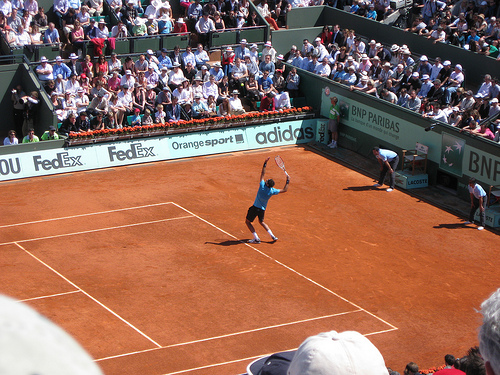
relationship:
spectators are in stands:
[34, 54, 54, 81] [24, 49, 310, 129]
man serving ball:
[243, 157, 291, 243] [266, 155, 275, 160]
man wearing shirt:
[243, 155, 291, 243] [251, 175, 280, 211]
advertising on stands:
[1, 118, 330, 180] [1, 0, 298, 145]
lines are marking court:
[0, 202, 399, 358] [1, 139, 498, 357]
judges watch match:
[372, 142, 489, 231] [77, 146, 373, 312]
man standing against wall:
[326, 94, 340, 152] [276, 59, 498, 212]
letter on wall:
[465, 147, 482, 178] [291, 66, 498, 220]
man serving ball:
[243, 155, 291, 243] [212, 95, 303, 168]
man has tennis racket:
[243, 157, 291, 243] [273, 152, 289, 177]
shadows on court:
[346, 180, 391, 197] [1, 139, 498, 357]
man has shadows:
[371, 144, 401, 192] [346, 180, 391, 197]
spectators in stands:
[0, 5, 497, 135] [3, 2, 497, 191]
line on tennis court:
[12, 192, 213, 252] [9, 146, 474, 369]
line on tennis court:
[61, 274, 403, 373] [9, 146, 474, 369]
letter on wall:
[53, 148, 60, 172] [0, 113, 322, 203]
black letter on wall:
[115, 148, 126, 160] [90, 147, 106, 163]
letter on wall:
[255, 130, 267, 145] [0, 115, 317, 180]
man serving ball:
[243, 155, 291, 243] [238, 80, 245, 87]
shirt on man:
[250, 189, 275, 208] [243, 165, 277, 240]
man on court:
[371, 146, 401, 193] [3, 161, 499, 372]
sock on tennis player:
[246, 232, 263, 246] [239, 143, 296, 257]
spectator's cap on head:
[246, 327, 388, 372] [258, 333, 393, 360]